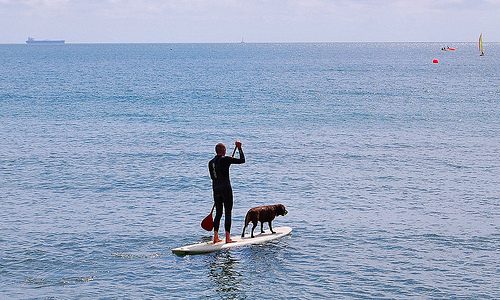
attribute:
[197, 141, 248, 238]
man — white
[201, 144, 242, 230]
paddle — red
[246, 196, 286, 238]
dog — brown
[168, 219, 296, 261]
board — white, yellow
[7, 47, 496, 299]
water — blue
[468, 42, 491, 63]
boat — yellow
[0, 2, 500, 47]
sky — white